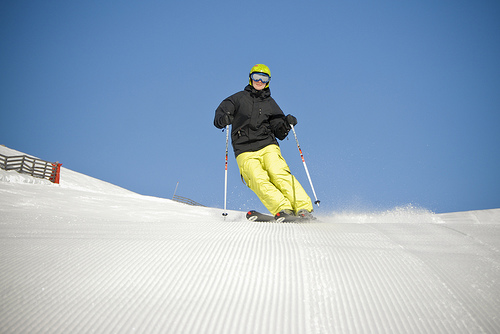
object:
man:
[211, 63, 313, 219]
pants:
[234, 144, 312, 215]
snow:
[0, 146, 498, 333]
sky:
[0, 0, 499, 215]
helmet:
[247, 63, 272, 89]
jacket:
[212, 84, 298, 159]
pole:
[288, 122, 323, 208]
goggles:
[247, 71, 271, 84]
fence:
[0, 154, 59, 185]